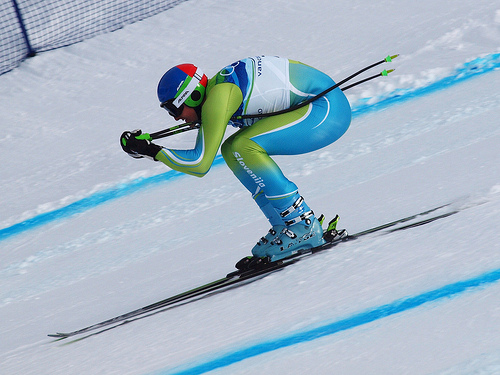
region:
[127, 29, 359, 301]
this is a man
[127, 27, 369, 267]
he is in a competition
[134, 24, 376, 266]
he is snow skating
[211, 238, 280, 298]
these are the skiis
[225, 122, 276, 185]
thee are the knees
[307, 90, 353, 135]
this is the butt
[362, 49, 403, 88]
these are the poles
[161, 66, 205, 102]
this is an helmet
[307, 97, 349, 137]
the costume is blue in colro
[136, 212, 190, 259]
the place is full of snow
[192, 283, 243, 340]
edge of a board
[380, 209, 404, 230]
part of a board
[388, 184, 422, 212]
part of a sniow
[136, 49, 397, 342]
lady is doing trick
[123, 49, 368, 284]
lady is om a skiingboard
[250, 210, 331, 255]
skking shoes are blue in color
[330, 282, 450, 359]
the floor has a blue line mark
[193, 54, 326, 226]
the outfit is blue and green in color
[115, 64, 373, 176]
lady is holding on the skiing sticks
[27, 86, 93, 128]
the floor is white in color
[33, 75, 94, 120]
floor is covered of snow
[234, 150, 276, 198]
words ar written in whit color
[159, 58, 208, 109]
helmet is blue and greeen in color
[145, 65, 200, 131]
red and blue helmet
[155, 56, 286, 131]
green and blue shirt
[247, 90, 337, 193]
green and blue pants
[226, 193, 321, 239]
blue and white boots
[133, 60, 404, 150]
person holds black poles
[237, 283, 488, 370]
blue lines on snow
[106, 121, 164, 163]
person has black gloves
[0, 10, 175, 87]
blue fence outside course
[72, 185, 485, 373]
person on black skis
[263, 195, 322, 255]
white snaps on boots